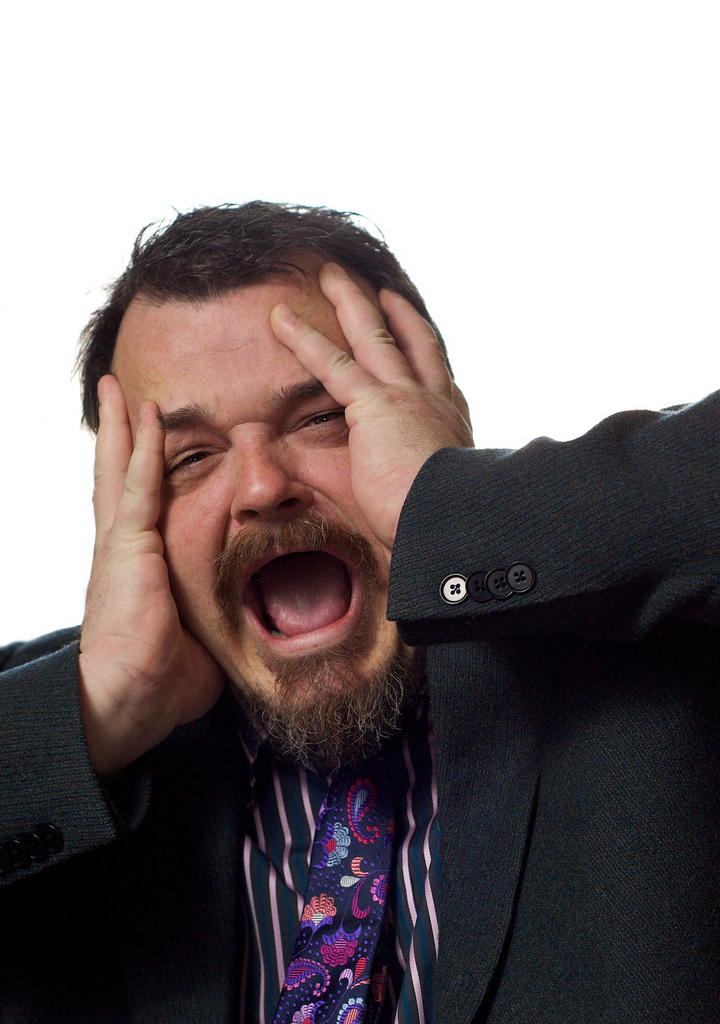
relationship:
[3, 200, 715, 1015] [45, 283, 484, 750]
man holdings hands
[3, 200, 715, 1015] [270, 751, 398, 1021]
man has tie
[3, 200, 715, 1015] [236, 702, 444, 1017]
man has shirt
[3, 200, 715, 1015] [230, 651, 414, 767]
man has beard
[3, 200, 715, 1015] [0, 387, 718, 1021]
man wearing jacket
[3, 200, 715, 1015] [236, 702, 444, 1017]
man wearing shirt